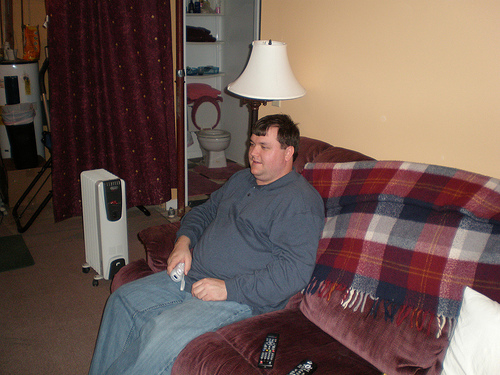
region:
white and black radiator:
[72, 163, 134, 290]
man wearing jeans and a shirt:
[82, 113, 327, 373]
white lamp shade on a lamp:
[220, 36, 305, 108]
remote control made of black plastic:
[257, 324, 282, 371]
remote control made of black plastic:
[284, 354, 321, 374]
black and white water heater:
[0, 53, 48, 162]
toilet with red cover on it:
[190, 93, 237, 170]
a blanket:
[351, 172, 448, 254]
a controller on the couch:
[251, 328, 287, 369]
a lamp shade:
[241, 48, 298, 95]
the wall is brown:
[361, 14, 458, 95]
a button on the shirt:
[241, 188, 253, 198]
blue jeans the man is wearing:
[149, 315, 185, 340]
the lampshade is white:
[242, 46, 290, 98]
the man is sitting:
[88, 112, 327, 373]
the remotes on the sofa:
[258, 330, 316, 372]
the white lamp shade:
[225, 39, 305, 99]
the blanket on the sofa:
[294, 158, 499, 340]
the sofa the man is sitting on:
[109, 135, 450, 372]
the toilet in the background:
[190, 94, 231, 169]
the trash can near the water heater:
[3, 102, 38, 164]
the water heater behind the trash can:
[3, 59, 45, 162]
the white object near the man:
[78, 166, 128, 285]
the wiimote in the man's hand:
[171, 259, 186, 291]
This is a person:
[93, 108, 318, 374]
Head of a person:
[235, 108, 310, 203]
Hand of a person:
[167, 198, 197, 286]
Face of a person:
[236, 125, 273, 180]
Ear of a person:
[278, 139, 296, 164]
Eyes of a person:
[246, 135, 271, 152]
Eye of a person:
[258, 141, 273, 154]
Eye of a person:
[249, 135, 255, 148]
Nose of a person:
[247, 148, 260, 160]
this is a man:
[37, 33, 484, 344]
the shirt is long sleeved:
[161, 171, 385, 351]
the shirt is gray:
[195, 180, 295, 281]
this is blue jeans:
[114, 273, 251, 371]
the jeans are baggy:
[124, 287, 221, 358]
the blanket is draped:
[350, 178, 490, 306]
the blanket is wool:
[334, 173, 439, 305]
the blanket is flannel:
[332, 171, 433, 323]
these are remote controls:
[222, 320, 323, 371]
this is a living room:
[56, 55, 413, 301]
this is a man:
[225, 123, 347, 298]